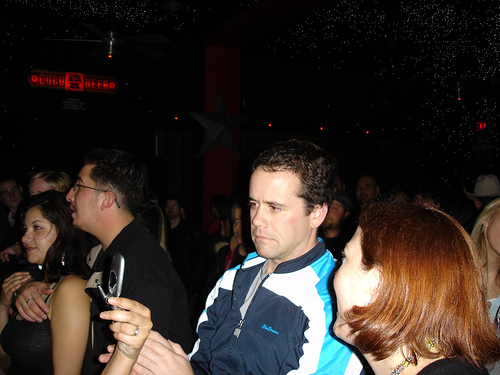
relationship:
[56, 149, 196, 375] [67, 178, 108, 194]
man wearing glasses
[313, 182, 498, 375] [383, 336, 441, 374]
woman wearing necklace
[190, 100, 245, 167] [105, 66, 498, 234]
star on wall